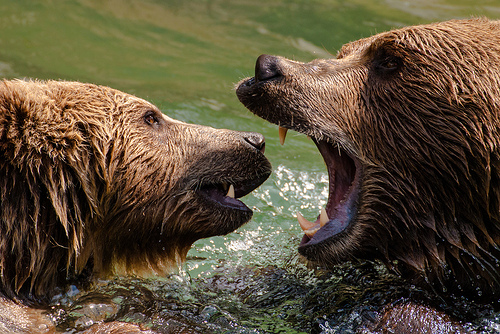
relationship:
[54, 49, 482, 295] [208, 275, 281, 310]
bears in water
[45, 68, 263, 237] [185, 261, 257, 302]
bear in water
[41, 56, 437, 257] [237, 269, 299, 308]
bears in water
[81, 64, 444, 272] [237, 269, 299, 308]
bears in water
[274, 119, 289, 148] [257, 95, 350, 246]
teeth in mouth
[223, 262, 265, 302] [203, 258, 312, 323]
bubbles on surface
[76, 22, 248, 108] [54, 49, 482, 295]
water behind bears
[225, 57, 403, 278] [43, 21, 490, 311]
mouth on bears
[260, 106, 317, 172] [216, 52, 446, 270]
tooth on bear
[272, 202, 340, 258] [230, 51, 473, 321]
teeth on bear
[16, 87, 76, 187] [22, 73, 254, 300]
fur on bear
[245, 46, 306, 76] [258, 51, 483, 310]
nose on bear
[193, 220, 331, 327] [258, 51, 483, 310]
water under bear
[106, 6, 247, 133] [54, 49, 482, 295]
water by bears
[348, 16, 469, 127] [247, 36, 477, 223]
eye on bear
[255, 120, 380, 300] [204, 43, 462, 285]
mouth on bear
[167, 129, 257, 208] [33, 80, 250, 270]
mouth on bear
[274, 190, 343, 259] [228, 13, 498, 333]
tooth on bear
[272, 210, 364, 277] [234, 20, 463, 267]
teeth on bear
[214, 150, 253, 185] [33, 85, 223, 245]
tooth on bear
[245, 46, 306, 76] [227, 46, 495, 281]
nose on bear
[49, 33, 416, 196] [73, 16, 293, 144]
bears in water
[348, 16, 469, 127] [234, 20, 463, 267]
eye on bear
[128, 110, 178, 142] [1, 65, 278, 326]
eye on bear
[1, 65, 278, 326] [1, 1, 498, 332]
bear in water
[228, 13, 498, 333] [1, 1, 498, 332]
bear in water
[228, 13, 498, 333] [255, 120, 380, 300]
bear has mouth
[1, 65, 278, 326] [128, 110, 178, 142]
bear has eye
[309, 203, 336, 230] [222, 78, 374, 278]
tooth in mouth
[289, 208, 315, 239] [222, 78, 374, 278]
tooth in mouth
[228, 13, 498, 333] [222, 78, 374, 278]
bear has mouth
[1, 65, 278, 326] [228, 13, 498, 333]
bear playing with bear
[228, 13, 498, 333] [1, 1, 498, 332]
bear swimming in water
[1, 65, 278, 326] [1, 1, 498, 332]
bear swimming in water